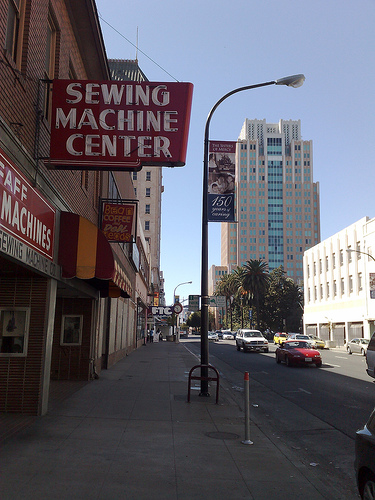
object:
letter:
[85, 83, 99, 105]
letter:
[101, 84, 124, 105]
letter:
[126, 84, 133, 105]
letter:
[135, 83, 149, 105]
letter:
[152, 85, 170, 106]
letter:
[56, 108, 77, 129]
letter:
[77, 108, 98, 130]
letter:
[99, 108, 116, 130]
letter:
[117, 109, 134, 131]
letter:
[136, 109, 143, 131]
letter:
[146, 109, 161, 131]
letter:
[164, 110, 178, 132]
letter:
[66, 132, 84, 155]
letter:
[101, 134, 116, 156]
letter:
[137, 136, 152, 158]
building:
[0, 0, 112, 416]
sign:
[151, 306, 172, 316]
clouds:
[237, 32, 280, 51]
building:
[302, 216, 375, 352]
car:
[275, 339, 322, 368]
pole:
[241, 370, 254, 444]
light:
[274, 72, 306, 88]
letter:
[84, 135, 100, 156]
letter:
[118, 135, 136, 158]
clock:
[173, 302, 183, 313]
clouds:
[184, 51, 237, 84]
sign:
[44, 79, 194, 171]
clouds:
[172, 231, 195, 274]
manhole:
[205, 431, 238, 439]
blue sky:
[95, 1, 374, 306]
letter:
[153, 135, 172, 157]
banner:
[206, 140, 238, 222]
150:
[211, 195, 232, 207]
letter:
[66, 82, 83, 104]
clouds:
[114, 7, 266, 77]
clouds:
[184, 20, 293, 101]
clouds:
[292, 109, 346, 142]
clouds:
[308, 31, 373, 65]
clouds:
[285, 27, 329, 61]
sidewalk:
[0, 334, 331, 499]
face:
[174, 305, 182, 312]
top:
[244, 372, 250, 380]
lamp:
[345, 248, 375, 260]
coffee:
[104, 204, 133, 240]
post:
[187, 74, 305, 405]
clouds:
[327, 89, 361, 155]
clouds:
[325, 57, 365, 142]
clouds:
[336, 83, 366, 146]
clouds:
[170, 191, 191, 262]